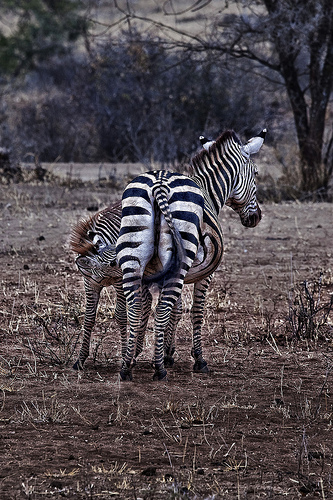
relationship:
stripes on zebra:
[171, 183, 207, 229] [74, 101, 305, 436]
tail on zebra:
[153, 186, 187, 290] [85, 110, 282, 397]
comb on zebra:
[178, 116, 238, 175] [106, 88, 294, 401]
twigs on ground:
[159, 402, 232, 457] [129, 392, 309, 496]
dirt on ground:
[61, 400, 272, 482] [51, 388, 264, 497]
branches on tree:
[108, 14, 221, 56] [92, 12, 282, 99]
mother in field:
[69, 128, 264, 373] [12, 72, 313, 429]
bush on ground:
[0, 417, 333, 500] [28, 396, 270, 489]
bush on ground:
[101, 439, 150, 480] [80, 354, 267, 483]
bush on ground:
[0, 417, 333, 500] [141, 375, 329, 497]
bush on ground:
[0, 417, 333, 500] [72, 400, 328, 496]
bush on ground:
[0, 417, 333, 500] [163, 379, 328, 463]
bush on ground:
[280, 268, 319, 347] [249, 261, 321, 331]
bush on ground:
[0, 417, 333, 500] [198, 302, 327, 414]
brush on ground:
[26, 275, 68, 346] [2, 179, 330, 498]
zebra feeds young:
[115, 125, 273, 384] [66, 194, 211, 373]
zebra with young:
[115, 125, 273, 384] [65, 182, 220, 376]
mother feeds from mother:
[69, 128, 264, 373] [114, 121, 270, 383]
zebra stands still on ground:
[115, 125, 273, 384] [2, 179, 330, 498]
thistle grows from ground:
[284, 270, 331, 346] [2, 179, 330, 498]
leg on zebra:
[148, 268, 178, 380] [115, 125, 273, 384]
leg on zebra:
[186, 268, 213, 375] [115, 125, 273, 384]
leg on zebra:
[112, 271, 131, 365] [62, 190, 222, 382]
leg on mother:
[70, 277, 102, 369] [69, 128, 264, 373]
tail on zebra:
[148, 179, 184, 289] [115, 125, 273, 384]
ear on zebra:
[241, 123, 273, 162] [115, 125, 273, 384]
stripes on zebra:
[215, 146, 241, 184] [115, 125, 273, 384]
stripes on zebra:
[170, 188, 207, 215] [115, 125, 273, 384]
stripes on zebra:
[114, 221, 150, 239] [115, 125, 273, 384]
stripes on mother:
[93, 219, 118, 246] [69, 128, 264, 373]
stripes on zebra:
[219, 144, 240, 175] [115, 125, 273, 384]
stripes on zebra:
[202, 155, 227, 204] [115, 125, 273, 384]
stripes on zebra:
[193, 161, 220, 214] [115, 125, 273, 384]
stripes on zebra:
[163, 170, 204, 193] [115, 125, 273, 384]